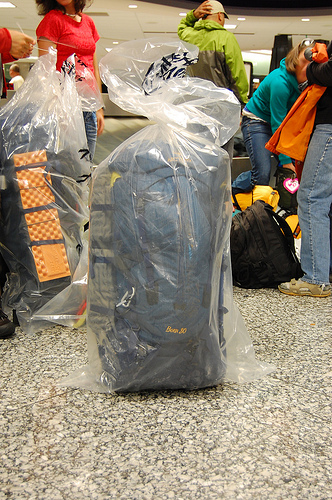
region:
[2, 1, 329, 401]
people waiting in line with luggage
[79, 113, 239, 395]
this pack is wrapped in plastic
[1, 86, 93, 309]
another pack wrapped in plastic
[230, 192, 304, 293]
a black backpack sits on the floor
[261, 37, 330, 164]
this traveler clutches an orange jacket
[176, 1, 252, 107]
this traveler is wearing a green jacket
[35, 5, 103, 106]
this traveler is wearing a red top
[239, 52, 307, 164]
this traveler is wearing a turquoise sweatshirt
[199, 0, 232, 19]
this traveler is wearing a cap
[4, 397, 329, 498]
the floor is a granite pattern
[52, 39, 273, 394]
Dufflebag in a large plastic bag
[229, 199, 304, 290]
Black backpack on the floor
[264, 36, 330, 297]
Person holding an orange jacket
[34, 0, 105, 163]
Woman wearing a red shirt and blue jeans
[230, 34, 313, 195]
Woman wearing a sweatshirt and blue jeans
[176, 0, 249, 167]
Man rubbing the back of his head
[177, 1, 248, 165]
Man wearing a green jacket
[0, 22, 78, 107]
Person tying the top of a plastic bag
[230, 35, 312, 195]
Woman picking up luggage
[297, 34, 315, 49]
Sunglasses on top of a head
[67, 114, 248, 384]
the luggage in plastic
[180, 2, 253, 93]
the man wearing the hat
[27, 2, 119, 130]
the woman wearing the red shirt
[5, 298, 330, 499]
tiles on the floor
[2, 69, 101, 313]
the luggage in plastic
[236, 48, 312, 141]
the woman wearing the hoodie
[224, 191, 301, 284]
the bag on the floor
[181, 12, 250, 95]
the man wearing green and gray jacket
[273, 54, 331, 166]
the person holding the orange jacket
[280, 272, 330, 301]
the person wearing socks and sandals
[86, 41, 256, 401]
a plastic bag with a hiking pack inside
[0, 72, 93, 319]
a plastic bag with a hiking pack inside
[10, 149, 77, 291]
a folded sleeping mat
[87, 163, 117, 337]
a folded sleeping mat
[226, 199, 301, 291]
a black backpack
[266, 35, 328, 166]
arm holding orange jacket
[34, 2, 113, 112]
woman wearing a red blouse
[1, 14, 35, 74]
hands of a person with red sleeves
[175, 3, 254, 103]
a man wearing a green jacket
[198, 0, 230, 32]
a man wearing a baseball cap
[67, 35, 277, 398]
blue luggage inside plastic bag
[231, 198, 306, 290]
black backpack next to person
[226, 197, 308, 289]
black backpack on floor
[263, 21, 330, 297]
person holding orange jacket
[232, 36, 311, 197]
person wearing teal hoodie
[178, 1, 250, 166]
man with hand on head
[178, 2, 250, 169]
man wearing green jacket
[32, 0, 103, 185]
woman wearing red top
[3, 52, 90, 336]
luggae inside plastic bag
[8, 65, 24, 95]
person wearing white shirt